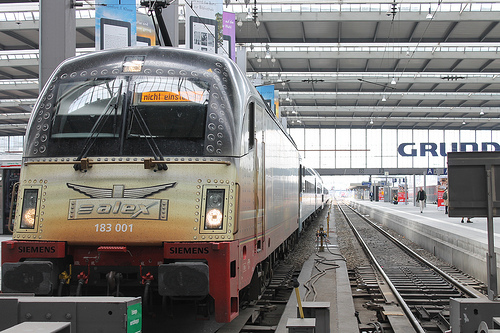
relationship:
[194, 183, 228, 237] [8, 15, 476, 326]
head light in photo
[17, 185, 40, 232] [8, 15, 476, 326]
headlights in photo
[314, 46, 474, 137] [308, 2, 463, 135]
lights attached to roof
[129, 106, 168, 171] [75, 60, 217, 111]
windshield wiper on windshield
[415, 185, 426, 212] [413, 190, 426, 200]
man walking in jacket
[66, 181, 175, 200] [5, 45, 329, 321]
wings on front of bus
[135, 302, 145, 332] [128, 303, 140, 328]
green sign with letters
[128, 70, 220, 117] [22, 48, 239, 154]
sign reflected in window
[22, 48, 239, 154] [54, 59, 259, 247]
window of train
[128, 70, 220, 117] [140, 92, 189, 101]
sign with letters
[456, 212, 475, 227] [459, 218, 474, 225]
feet in shoes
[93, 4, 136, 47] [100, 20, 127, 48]
sign with phone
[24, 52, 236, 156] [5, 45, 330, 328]
front window of bus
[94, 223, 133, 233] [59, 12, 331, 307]
number painted on train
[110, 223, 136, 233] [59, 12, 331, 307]
number painted on train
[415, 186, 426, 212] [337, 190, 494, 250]
man walking platform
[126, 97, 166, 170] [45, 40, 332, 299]
windshield wiper on train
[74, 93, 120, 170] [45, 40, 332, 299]
windshield wiper on train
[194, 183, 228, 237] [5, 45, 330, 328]
head light of bus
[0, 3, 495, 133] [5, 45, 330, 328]
roof above bus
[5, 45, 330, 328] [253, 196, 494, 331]
bus on tracks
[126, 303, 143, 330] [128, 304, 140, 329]
stick with lettering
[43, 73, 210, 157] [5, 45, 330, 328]
window on bus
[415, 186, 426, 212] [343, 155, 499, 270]
man on platform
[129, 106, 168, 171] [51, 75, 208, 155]
windshield wiper on window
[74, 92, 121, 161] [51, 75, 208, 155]
windshield wiper on window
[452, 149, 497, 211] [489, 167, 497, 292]
sign on pole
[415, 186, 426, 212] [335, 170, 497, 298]
man on platform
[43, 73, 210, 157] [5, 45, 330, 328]
window of bus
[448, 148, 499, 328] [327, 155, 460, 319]
metal plate attached to train tracks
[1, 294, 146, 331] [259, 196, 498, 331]
metal structure at end of train tracks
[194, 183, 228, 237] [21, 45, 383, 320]
head light on train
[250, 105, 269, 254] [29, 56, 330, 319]
door on train